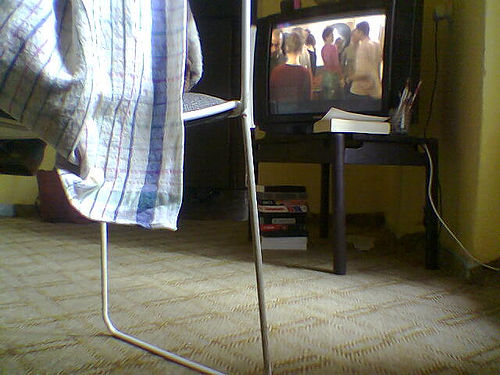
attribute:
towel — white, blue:
[5, 3, 207, 246]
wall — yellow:
[422, 2, 497, 267]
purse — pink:
[31, 167, 87, 225]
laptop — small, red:
[30, 169, 95, 227]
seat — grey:
[164, 85, 232, 125]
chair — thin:
[172, 7, 285, 296]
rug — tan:
[293, 318, 360, 370]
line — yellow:
[295, 320, 318, 335]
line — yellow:
[346, 335, 362, 350]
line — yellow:
[281, 352, 309, 369]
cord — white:
[415, 136, 498, 276]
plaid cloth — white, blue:
[1, 0, 203, 230]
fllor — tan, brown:
[86, 194, 374, 374]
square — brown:
[304, 321, 359, 348]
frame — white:
[96, 3, 283, 363]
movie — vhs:
[255, 201, 317, 216]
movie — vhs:
[256, 223, 304, 233]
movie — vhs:
[254, 192, 306, 197]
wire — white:
[412, 132, 484, 262]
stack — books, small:
[254, 177, 318, 260]